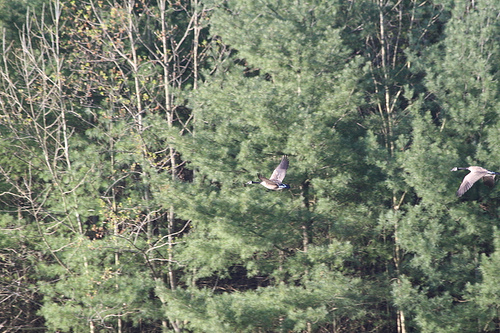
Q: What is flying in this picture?
A: Geese.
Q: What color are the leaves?
A: Green.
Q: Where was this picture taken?
A: The forest.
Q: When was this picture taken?
A: Daytime.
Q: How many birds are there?
A: Two.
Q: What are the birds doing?
A: Flying.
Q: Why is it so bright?
A: Because it's daytime.